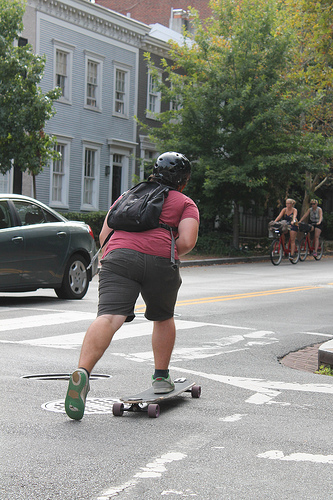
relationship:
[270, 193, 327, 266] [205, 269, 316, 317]
cyclist in street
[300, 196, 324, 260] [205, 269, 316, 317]
cyclist in street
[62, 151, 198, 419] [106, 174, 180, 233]
person wearing backpack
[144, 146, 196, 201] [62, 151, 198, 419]
head of person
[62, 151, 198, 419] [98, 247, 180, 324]
person wearing pants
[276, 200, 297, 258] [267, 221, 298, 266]
woman riding bicycle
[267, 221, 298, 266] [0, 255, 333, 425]
bicycle in street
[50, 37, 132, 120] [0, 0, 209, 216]
windows on building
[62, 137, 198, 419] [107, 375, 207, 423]
person riding skateboard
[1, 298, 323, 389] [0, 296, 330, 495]
crosswalk in pavement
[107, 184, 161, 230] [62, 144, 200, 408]
backpack of skateboarder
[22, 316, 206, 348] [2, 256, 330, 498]
line on ground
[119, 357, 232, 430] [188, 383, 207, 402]
skateboard with wheel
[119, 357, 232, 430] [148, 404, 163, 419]
skateboard with wheels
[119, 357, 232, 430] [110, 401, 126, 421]
skateboard with wheel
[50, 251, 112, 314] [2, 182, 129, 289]
wheel on car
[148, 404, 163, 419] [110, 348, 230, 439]
wheels on board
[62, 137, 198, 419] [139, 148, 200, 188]
person wearing helmet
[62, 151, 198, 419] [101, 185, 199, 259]
person wearing t-shirt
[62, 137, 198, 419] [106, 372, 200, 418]
person riding skateboard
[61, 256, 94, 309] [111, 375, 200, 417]
wheel on skateboard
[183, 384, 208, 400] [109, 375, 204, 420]
wheel on skateboard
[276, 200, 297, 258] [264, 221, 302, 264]
woman riding bicycle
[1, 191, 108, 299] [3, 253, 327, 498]
car in street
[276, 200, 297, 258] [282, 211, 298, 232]
woman wearing dress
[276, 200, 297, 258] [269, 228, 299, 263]
woman riding bicycle